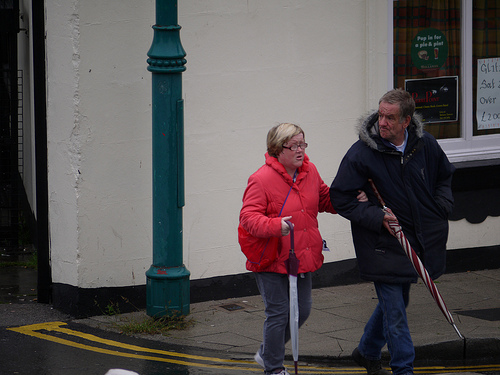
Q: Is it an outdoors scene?
A: Yes, it is outdoors.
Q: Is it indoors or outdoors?
A: It is outdoors.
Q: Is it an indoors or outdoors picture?
A: It is outdoors.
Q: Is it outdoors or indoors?
A: It is outdoors.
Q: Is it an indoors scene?
A: No, it is outdoors.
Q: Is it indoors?
A: No, it is outdoors.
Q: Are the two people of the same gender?
A: No, they are both male and female.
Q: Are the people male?
A: No, they are both male and female.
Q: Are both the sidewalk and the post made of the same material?
A: No, the sidewalk is made of concrete and the post is made of metal.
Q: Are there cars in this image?
A: No, there are no cars.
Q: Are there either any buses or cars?
A: No, there are no cars or buses.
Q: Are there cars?
A: No, there are no cars.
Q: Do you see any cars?
A: No, there are no cars.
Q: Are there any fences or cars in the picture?
A: No, there are no cars or fences.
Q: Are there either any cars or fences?
A: No, there are no cars or fences.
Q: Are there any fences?
A: No, there are no fences.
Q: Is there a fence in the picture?
A: No, there are no fences.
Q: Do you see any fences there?
A: No, there are no fences.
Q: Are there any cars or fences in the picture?
A: No, there are no fences or cars.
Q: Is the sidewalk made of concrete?
A: Yes, the sidewalk is made of concrete.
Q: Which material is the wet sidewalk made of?
A: The sidewalk is made of concrete.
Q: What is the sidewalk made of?
A: The sidewalk is made of concrete.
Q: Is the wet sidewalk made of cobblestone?
A: No, the sidewalk is made of concrete.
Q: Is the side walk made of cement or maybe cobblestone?
A: The side walk is made of cement.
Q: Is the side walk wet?
A: Yes, the side walk is wet.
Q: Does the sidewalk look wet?
A: Yes, the sidewalk is wet.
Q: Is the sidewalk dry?
A: No, the sidewalk is wet.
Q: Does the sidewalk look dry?
A: No, the sidewalk is wet.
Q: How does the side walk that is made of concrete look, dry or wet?
A: The sidewalk is wet.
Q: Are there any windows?
A: Yes, there is a window.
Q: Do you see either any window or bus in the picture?
A: Yes, there is a window.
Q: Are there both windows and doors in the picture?
A: No, there is a window but no doors.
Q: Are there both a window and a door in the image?
A: No, there is a window but no doors.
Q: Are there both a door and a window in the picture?
A: No, there is a window but no doors.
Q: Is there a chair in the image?
A: No, there are no chairs.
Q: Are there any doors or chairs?
A: No, there are no chairs or doors.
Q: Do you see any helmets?
A: No, there are no helmets.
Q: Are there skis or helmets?
A: No, there are no helmets or skis.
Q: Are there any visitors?
A: No, there are no visitors.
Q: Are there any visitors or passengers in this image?
A: No, there are no visitors or passengers.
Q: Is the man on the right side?
A: Yes, the man is on the right of the image.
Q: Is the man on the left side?
A: No, the man is on the right of the image.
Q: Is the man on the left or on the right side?
A: The man is on the right of the image.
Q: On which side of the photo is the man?
A: The man is on the right of the image.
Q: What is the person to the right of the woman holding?
A: The man is holding the umbrella.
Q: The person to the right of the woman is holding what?
A: The man is holding the umbrella.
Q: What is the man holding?
A: The man is holding the umbrella.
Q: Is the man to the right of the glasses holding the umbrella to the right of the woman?
A: Yes, the man is holding the umbrella.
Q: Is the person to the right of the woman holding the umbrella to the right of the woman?
A: Yes, the man is holding the umbrella.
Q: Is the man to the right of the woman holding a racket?
A: No, the man is holding the umbrella.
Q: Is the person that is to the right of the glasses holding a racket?
A: No, the man is holding the umbrella.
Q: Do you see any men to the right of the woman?
A: Yes, there is a man to the right of the woman.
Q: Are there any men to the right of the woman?
A: Yes, there is a man to the right of the woman.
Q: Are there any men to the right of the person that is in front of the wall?
A: Yes, there is a man to the right of the woman.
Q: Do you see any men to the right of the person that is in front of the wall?
A: Yes, there is a man to the right of the woman.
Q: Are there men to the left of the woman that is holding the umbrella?
A: No, the man is to the right of the woman.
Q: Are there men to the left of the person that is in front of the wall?
A: No, the man is to the right of the woman.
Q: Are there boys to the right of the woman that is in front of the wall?
A: No, there is a man to the right of the woman.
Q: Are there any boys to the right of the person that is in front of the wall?
A: No, there is a man to the right of the woman.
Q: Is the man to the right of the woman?
A: Yes, the man is to the right of the woman.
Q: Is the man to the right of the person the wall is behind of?
A: Yes, the man is to the right of the woman.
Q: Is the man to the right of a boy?
A: No, the man is to the right of the woman.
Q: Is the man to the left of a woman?
A: No, the man is to the right of a woman.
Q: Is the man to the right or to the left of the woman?
A: The man is to the right of the woman.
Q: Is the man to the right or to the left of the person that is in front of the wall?
A: The man is to the right of the woman.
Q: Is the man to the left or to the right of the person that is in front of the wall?
A: The man is to the right of the woman.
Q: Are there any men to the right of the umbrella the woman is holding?
A: Yes, there is a man to the right of the umbrella.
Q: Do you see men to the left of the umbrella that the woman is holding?
A: No, the man is to the right of the umbrella.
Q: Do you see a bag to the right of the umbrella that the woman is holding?
A: No, there is a man to the right of the umbrella.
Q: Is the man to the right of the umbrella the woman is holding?
A: Yes, the man is to the right of the umbrella.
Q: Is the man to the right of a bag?
A: No, the man is to the right of the umbrella.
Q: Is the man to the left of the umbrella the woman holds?
A: No, the man is to the right of the umbrella.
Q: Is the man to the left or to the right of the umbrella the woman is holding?
A: The man is to the right of the umbrella.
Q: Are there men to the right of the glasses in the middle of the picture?
A: Yes, there is a man to the right of the glasses.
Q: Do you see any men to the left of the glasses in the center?
A: No, the man is to the right of the glasses.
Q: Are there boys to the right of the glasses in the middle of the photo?
A: No, there is a man to the right of the glasses.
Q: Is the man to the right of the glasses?
A: Yes, the man is to the right of the glasses.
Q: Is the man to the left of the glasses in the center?
A: No, the man is to the right of the glasses.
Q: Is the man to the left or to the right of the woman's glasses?
A: The man is to the right of the glasses.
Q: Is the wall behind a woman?
A: Yes, the wall is behind a woman.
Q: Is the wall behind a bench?
A: No, the wall is behind a woman.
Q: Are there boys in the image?
A: No, there are no boys.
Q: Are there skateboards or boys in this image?
A: No, there are no boys or skateboards.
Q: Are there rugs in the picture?
A: No, there are no rugs.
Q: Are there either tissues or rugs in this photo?
A: No, there are no rugs or tissues.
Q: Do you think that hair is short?
A: Yes, the hair is short.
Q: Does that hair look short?
A: Yes, the hair is short.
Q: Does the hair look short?
A: Yes, the hair is short.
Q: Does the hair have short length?
A: Yes, the hair is short.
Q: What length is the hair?
A: The hair is short.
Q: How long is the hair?
A: The hair is short.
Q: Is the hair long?
A: No, the hair is short.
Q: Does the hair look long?
A: No, the hair is short.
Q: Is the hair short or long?
A: The hair is short.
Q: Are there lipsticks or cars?
A: No, there are no cars or lipsticks.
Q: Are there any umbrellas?
A: Yes, there is an umbrella.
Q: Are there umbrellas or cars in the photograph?
A: Yes, there is an umbrella.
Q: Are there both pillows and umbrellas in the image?
A: No, there is an umbrella but no pillows.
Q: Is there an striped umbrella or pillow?
A: Yes, there is a striped umbrella.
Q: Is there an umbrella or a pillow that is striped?
A: Yes, the umbrella is striped.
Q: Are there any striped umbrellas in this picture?
A: Yes, there is a striped umbrella.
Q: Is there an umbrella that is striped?
A: Yes, there is an umbrella that is striped.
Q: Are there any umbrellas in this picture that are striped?
A: Yes, there is an umbrella that is striped.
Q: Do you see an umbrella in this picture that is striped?
A: Yes, there is an umbrella that is striped.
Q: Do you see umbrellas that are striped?
A: Yes, there is an umbrella that is striped.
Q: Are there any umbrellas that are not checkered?
A: Yes, there is a striped umbrella.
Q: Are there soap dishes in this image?
A: No, there are no soap dishes.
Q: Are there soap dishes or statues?
A: No, there are no soap dishes or statues.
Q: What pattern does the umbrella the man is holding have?
A: The umbrella has striped pattern.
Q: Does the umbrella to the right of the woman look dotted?
A: No, the umbrella is striped.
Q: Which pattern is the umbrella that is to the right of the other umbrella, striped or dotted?
A: The umbrella is striped.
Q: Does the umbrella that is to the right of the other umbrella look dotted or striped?
A: The umbrella is striped.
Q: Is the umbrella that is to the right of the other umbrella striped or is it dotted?
A: The umbrella is striped.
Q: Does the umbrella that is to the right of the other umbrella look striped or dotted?
A: The umbrella is striped.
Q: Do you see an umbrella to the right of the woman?
A: Yes, there is an umbrella to the right of the woman.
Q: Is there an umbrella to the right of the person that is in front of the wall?
A: Yes, there is an umbrella to the right of the woman.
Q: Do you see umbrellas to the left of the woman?
A: No, the umbrella is to the right of the woman.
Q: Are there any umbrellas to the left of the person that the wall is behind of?
A: No, the umbrella is to the right of the woman.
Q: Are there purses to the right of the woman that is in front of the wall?
A: No, there is an umbrella to the right of the woman.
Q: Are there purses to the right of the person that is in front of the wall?
A: No, there is an umbrella to the right of the woman.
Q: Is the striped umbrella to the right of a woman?
A: Yes, the umbrella is to the right of a woman.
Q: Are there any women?
A: Yes, there is a woman.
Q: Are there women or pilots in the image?
A: Yes, there is a woman.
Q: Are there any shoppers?
A: No, there are no shoppers.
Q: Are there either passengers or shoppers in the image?
A: No, there are no shoppers or passengers.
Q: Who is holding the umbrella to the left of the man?
A: The woman is holding the umbrella.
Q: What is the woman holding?
A: The woman is holding the umbrella.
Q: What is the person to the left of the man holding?
A: The woman is holding the umbrella.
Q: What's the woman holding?
A: The woman is holding the umbrella.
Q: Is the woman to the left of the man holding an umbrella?
A: Yes, the woman is holding an umbrella.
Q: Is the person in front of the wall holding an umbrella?
A: Yes, the woman is holding an umbrella.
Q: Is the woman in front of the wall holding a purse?
A: No, the woman is holding an umbrella.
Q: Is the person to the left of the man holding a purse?
A: No, the woman is holding an umbrella.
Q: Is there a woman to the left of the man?
A: Yes, there is a woman to the left of the man.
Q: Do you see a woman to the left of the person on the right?
A: Yes, there is a woman to the left of the man.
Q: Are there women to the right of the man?
A: No, the woman is to the left of the man.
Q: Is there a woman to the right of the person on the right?
A: No, the woman is to the left of the man.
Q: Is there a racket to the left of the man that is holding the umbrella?
A: No, there is a woman to the left of the man.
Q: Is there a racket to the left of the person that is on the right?
A: No, there is a woman to the left of the man.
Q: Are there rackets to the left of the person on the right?
A: No, there is a woman to the left of the man.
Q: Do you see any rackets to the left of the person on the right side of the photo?
A: No, there is a woman to the left of the man.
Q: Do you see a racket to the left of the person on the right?
A: No, there is a woman to the left of the man.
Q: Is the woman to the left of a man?
A: Yes, the woman is to the left of a man.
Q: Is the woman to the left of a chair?
A: No, the woman is to the left of a man.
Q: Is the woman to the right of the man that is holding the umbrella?
A: No, the woman is to the left of the man.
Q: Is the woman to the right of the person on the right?
A: No, the woman is to the left of the man.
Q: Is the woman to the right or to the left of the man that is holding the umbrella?
A: The woman is to the left of the man.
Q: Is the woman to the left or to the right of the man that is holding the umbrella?
A: The woman is to the left of the man.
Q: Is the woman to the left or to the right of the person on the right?
A: The woman is to the left of the man.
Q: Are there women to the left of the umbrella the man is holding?
A: Yes, there is a woman to the left of the umbrella.